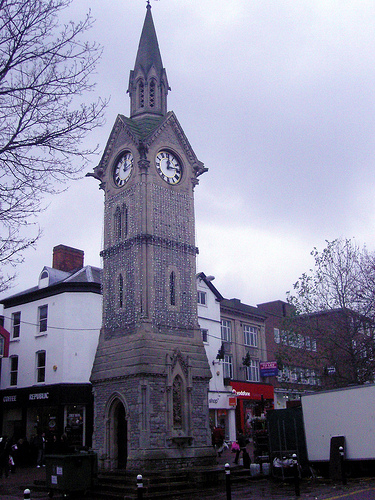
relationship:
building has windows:
[0, 241, 96, 459] [8, 305, 57, 393]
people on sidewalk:
[2, 421, 71, 453] [4, 461, 51, 487]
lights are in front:
[104, 182, 196, 330] [104, 193, 144, 331]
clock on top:
[105, 149, 139, 189] [105, 147, 195, 198]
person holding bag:
[232, 426, 253, 465] [229, 441, 243, 455]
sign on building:
[257, 358, 281, 380] [219, 298, 272, 387]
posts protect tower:
[17, 445, 362, 498] [83, 2, 222, 468]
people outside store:
[2, 421, 71, 453] [0, 241, 96, 459]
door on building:
[102, 387, 136, 471] [83, 2, 222, 468]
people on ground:
[2, 421, 71, 453] [3, 470, 368, 499]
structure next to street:
[293, 384, 375, 470] [298, 482, 374, 498]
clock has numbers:
[105, 149, 139, 189] [116, 155, 132, 161]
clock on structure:
[105, 149, 139, 189] [83, 2, 222, 468]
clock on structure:
[150, 144, 186, 190] [83, 2, 222, 468]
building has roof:
[0, 241, 96, 459] [2, 264, 103, 309]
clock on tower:
[105, 149, 139, 189] [83, 2, 222, 468]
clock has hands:
[105, 149, 139, 189] [121, 156, 135, 170]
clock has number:
[105, 149, 139, 189] [121, 155, 129, 160]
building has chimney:
[0, 241, 96, 459] [49, 243, 93, 273]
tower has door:
[83, 2, 222, 468] [102, 387, 136, 471]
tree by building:
[0, 0, 105, 307] [0, 241, 96, 459]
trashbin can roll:
[269, 408, 305, 487] [271, 466, 303, 486]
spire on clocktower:
[130, 1, 168, 118] [83, 2, 222, 468]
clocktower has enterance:
[83, 2, 222, 468] [102, 387, 136, 471]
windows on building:
[8, 305, 57, 393] [0, 241, 96, 459]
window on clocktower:
[130, 73, 167, 114] [83, 2, 222, 468]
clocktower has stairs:
[83, 2, 222, 468] [99, 458, 252, 492]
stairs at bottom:
[99, 458, 252, 492] [86, 447, 258, 487]